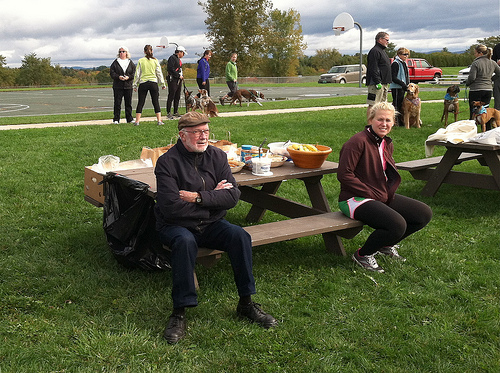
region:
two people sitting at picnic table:
[154, 98, 424, 336]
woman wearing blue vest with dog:
[388, 40, 425, 122]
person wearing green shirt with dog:
[218, 49, 268, 109]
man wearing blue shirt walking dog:
[195, 48, 218, 111]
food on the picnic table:
[223, 142, 325, 173]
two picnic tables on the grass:
[82, 111, 497, 276]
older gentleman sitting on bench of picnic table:
[149, 109, 275, 343]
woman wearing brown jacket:
[337, 103, 442, 270]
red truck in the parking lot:
[404, 53, 441, 80]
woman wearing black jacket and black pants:
[112, 50, 134, 125]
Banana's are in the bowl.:
[278, 136, 338, 171]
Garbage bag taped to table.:
[94, 170, 160, 254]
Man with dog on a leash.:
[166, 46, 197, 113]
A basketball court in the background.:
[323, 10, 361, 97]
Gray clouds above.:
[40, 15, 222, 53]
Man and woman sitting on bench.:
[178, 106, 428, 259]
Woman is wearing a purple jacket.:
[188, 44, 218, 101]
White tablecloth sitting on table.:
[433, 126, 498, 161]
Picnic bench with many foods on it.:
[230, 144, 342, 265]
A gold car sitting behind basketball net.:
[318, 58, 368, 92]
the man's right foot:
[158, 308, 190, 344]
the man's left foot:
[239, 298, 276, 330]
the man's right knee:
[175, 230, 197, 255]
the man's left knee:
[222, 222, 254, 258]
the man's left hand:
[176, 187, 194, 205]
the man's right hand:
[216, 175, 233, 195]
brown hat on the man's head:
[175, 111, 212, 129]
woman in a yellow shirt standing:
[131, 43, 168, 122]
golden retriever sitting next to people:
[401, 79, 426, 133]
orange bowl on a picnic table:
[287, 139, 333, 171]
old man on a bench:
[145, 110, 281, 353]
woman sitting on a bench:
[325, 92, 436, 272]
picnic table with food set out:
[87, 142, 337, 238]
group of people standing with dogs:
[95, 30, 275, 125]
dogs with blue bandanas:
[427, 80, 497, 127]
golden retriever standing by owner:
[396, 77, 422, 132]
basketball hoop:
[322, 10, 363, 95]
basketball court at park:
[0, 8, 391, 113]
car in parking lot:
[313, 55, 368, 86]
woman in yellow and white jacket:
[133, 44, 168, 126]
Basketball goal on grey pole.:
[326, 5, 368, 82]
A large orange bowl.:
[287, 139, 330, 169]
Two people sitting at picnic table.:
[91, 91, 425, 343]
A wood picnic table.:
[103, 118, 372, 267]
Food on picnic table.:
[133, 115, 349, 251]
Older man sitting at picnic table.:
[138, 106, 280, 349]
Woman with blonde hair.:
[329, 88, 439, 280]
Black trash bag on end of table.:
[96, 167, 171, 279]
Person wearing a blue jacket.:
[194, 45, 221, 101]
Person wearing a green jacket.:
[222, 50, 244, 96]